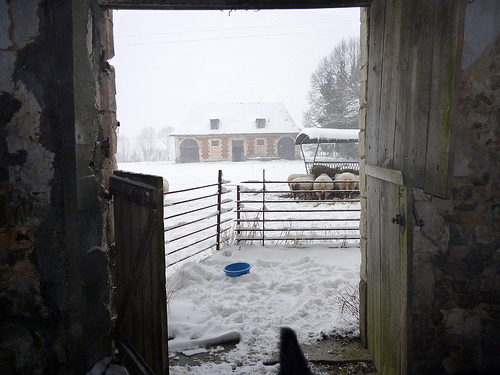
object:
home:
[171, 101, 312, 179]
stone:
[280, 325, 315, 375]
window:
[207, 140, 228, 150]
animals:
[287, 166, 361, 204]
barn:
[0, 0, 499, 375]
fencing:
[163, 164, 358, 267]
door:
[254, 137, 270, 156]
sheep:
[292, 175, 317, 202]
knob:
[391, 210, 407, 228]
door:
[352, 162, 417, 370]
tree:
[302, 33, 365, 135]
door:
[349, 4, 469, 373]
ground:
[164, 240, 362, 338]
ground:
[126, 157, 309, 195]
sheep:
[285, 174, 308, 186]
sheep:
[311, 173, 336, 200]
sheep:
[335, 175, 356, 196]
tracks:
[263, 257, 336, 307]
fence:
[234, 176, 367, 247]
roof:
[167, 108, 299, 137]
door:
[109, 163, 177, 374]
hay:
[305, 159, 365, 178]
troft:
[294, 124, 358, 176]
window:
[252, 137, 267, 146]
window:
[229, 138, 247, 148]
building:
[170, 101, 296, 162]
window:
[207, 115, 225, 132]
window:
[167, 139, 188, 148]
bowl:
[223, 262, 254, 278]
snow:
[181, 245, 350, 325]